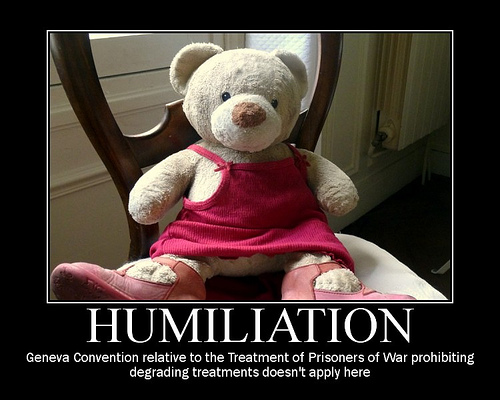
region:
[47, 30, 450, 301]
teddy bear in pink dress sitting on a chair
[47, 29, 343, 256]
the wood chair back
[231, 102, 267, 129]
the brown nose on the teddy bear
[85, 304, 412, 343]
a word in large white letters under the teddy bear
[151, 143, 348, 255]
pink dress on the teddy bear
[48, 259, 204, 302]
the teddy bear's light pink shoe on the left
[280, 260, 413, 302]
the teddy bear's light pink shoe on the right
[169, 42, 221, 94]
the left ear on the teddy bear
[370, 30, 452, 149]
wall radiator on the right side of the teddy bear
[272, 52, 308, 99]
right ear on the teddy bear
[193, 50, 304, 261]
tan bear in dress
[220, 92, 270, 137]
tan bear with brown nose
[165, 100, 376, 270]
teddy bear wearing red dress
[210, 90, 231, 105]
teddy bear with black eyes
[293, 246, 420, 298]
teddy bear wearing shoes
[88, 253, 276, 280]
teddy bear wearing red shoes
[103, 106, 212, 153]
brown wooden back chair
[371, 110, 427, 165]
plug in white radiator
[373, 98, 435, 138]
white radiator on wall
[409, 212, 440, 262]
dark floor in background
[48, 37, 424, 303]
A stuffed animal in the foreground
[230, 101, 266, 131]
Teddy bear's nose is brown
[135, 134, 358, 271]
Teddy bear is wearing a dress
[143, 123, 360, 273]
The dress is pink in color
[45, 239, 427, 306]
Teddy bear's shoes are pink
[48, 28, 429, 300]
Teddy bear is white in color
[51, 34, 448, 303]
Bear is sitting in a chair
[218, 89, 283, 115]
Teddy bear's eyes are black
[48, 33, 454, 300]
Photo was taken in the daytime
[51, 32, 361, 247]
Top of chair is made out of wood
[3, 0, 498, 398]
A motivational poster about humiliation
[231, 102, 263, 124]
The nose of the stuffed bear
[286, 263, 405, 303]
A pink shoe on the bear's left foot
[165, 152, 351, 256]
The stuffed bear has a dress on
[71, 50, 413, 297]
A stuffed bear in a dress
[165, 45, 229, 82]
The right ear of the stuffed bear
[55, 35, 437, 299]
A stuffed bear on a chair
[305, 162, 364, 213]
The left arm of the stuffed bear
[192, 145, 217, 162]
A strap on the tiny dress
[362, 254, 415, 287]
The seat of the chair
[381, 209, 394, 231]
part of the floor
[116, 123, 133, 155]
part of a chair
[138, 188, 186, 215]
part of a doll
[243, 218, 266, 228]
part of a cloth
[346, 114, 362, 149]
part of a door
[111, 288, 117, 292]
part of a shoe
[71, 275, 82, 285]
part of a sole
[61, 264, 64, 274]
tip of a sole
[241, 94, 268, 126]
nose of a doll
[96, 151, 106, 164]
edge of a chair